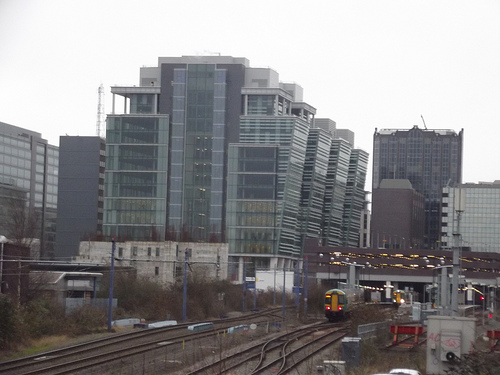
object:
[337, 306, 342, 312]
headlights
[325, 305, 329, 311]
headlights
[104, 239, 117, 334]
post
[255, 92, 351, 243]
building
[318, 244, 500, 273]
garage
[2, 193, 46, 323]
trees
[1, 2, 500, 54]
sky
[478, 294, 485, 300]
light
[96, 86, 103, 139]
antenna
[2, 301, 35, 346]
bushes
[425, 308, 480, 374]
panel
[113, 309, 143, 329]
trailer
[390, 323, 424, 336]
sign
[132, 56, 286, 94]
tower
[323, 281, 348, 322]
train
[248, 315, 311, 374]
tracks